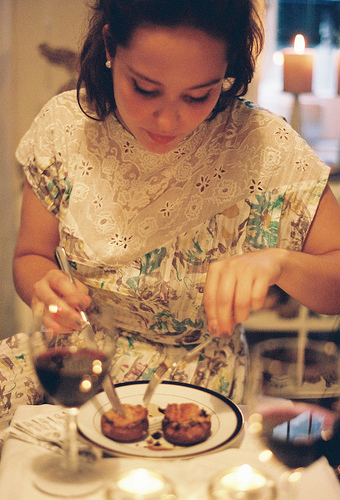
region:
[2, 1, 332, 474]
woman cutting food on plate at table with knife and fork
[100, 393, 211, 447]
two crab cakes on plate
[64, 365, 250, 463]
round black and white plate with two crab cakes on it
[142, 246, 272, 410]
hand holding silver knife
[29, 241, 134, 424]
hand holding silver knife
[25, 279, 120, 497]
glass of red wine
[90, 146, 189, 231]
lace on front of dress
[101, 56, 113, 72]
small pearl ear ring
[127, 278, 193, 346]
green and brown floral pattern n white dress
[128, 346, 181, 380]
pleats in skirt portion of dress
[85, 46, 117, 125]
Woman has dark hair.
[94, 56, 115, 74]
Large earring on woman's ear.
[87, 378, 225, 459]
White plate on table.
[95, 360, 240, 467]
Dark stripe around plate.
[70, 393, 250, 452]
Edge of plate has gold stripe.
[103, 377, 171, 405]
Person holding knife and fork.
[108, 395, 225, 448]
2 crab cakes sitting on plate.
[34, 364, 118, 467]
Glass of red wine on table.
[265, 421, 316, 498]
Glass of red wine sitting on table.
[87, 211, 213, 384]
Woman is wearing a light printed dress.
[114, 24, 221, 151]
the face of a woman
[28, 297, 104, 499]
a partially full wine glass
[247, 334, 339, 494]
a partially full wine glass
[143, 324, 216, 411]
a silver metal fork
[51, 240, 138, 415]
a silver metal knife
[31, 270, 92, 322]
the hand of a woman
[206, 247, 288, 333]
the hand of a woman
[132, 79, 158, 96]
the eye of a woman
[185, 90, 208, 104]
the eye of a woman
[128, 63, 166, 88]
the eyebrow of a woman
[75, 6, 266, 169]
lady wearing white earrings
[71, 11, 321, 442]
lady cutting food on plate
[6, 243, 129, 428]
hand holding knife on food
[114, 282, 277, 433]
hand holding fork above food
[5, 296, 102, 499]
glass of red wine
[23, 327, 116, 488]
glass of wine on table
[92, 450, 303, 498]
lit candles on table top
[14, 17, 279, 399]
decorative top on dress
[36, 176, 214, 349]
green and brown on dress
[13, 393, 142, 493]
napkin folded on table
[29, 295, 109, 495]
a glass of red wine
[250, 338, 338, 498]
a glass of red wine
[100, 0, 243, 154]
the face of a young woman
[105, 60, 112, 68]
a woman's pearl earing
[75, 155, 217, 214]
white lace fabric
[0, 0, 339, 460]
a woman cutting into food on a plate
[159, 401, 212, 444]
circular fried food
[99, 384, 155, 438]
a knife and fork cutting into food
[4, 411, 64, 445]
the corner of a napkin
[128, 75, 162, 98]
the closed eye of a young woman